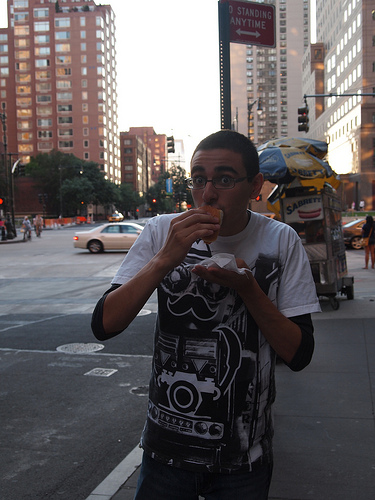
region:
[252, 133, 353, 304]
Hotdog stand behind man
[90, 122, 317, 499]
Man eating a hotdog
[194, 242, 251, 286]
Napkin in man's hand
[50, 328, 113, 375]
Covered sewer in street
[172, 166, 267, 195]
Glasses on man's face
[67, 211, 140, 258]
Tan car on road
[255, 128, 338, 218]
Yellow and blue umbrellas on stand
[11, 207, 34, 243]
Man riding a bicycle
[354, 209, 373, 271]
Woman wearing blue shirt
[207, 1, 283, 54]
Red sign on pole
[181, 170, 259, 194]
A man in spectacles on his face.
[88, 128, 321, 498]
A young man eating a hot dog.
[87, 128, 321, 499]
A man walking the street eating a hot dog.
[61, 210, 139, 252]
A vehicle turning in the middle of the road.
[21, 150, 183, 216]
Trees next to the buildings.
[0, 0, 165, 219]
Tall buildings on the side of the road.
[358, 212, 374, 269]
A woman with orange pants.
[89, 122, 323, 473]
A man in a black and white t-shirt.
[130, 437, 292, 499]
A young man wearing blue jeans.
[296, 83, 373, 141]
Street lights placed high on the road.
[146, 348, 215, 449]
A camera print is visible.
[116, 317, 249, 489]
A camera print is visible.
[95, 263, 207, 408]
A camera print is visible.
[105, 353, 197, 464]
A camera print is visible.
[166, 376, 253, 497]
A camera print is visible.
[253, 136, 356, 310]
hot dog wheel cart on sidewalk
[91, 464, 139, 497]
white lines drawn in street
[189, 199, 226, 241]
partially eaten hot dog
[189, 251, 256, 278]
white paper napkin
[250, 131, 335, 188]
blue and yellow umbrella on top of hot dog stand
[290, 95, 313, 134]
black three part traffic light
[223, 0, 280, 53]
red and white traffic sign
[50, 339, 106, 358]
metal manhole in street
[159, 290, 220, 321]
black mustache on shirt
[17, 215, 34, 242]
person on bicycle in street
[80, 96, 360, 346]
the man makes a face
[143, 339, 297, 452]
black and white graphics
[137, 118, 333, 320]
he is eating food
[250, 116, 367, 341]
a hot dog cart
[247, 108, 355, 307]
the umbrella is yellow and blue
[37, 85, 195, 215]
the buildings are red brick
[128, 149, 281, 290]
the man wears glasses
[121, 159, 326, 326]
he is eating a hot dog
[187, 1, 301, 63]
the sign is red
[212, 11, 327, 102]
the sign says no standing anytime